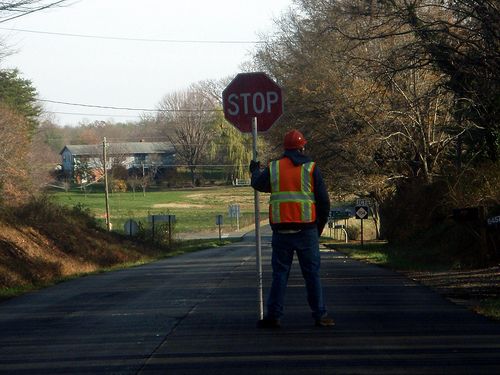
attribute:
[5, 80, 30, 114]
leaves — brown, green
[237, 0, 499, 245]
tree — large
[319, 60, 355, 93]
leaves — orange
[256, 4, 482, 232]
leaves — green, brown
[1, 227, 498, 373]
gray road — paved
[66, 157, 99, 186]
window — backs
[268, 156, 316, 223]
vest — orange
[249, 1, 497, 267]
trees — brown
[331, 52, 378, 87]
leaves — green, brown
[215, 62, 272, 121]
stop sign — red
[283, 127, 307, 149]
hat — red, hard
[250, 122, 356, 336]
worker — yellow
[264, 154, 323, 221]
vest — orange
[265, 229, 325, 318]
jeans — blue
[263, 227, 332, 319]
jeans — blue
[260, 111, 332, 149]
hat — red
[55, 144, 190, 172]
house — blue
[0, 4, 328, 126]
cloud — white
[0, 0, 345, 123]
sky — blue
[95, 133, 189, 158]
roof — slanted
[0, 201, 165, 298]
hill — dried, grassy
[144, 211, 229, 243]
signs — three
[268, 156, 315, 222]
stripes — silver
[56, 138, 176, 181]
house — large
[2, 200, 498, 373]
road — gray